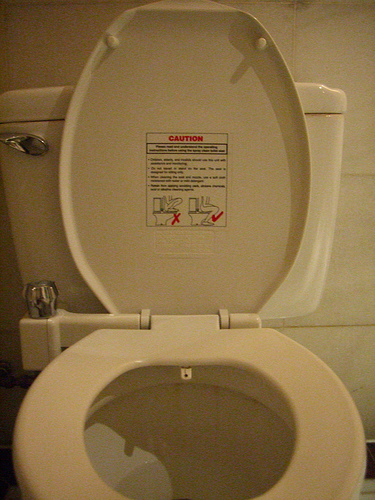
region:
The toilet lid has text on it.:
[105, 90, 255, 250]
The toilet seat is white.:
[7, 325, 362, 494]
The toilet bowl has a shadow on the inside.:
[96, 364, 283, 490]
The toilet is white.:
[4, 3, 367, 494]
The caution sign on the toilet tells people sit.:
[124, 109, 244, 247]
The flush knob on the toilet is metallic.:
[0, 124, 52, 169]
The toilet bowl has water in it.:
[90, 354, 286, 495]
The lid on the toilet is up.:
[13, 0, 359, 327]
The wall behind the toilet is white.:
[7, 8, 368, 323]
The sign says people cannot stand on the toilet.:
[132, 121, 242, 238]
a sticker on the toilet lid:
[139, 127, 235, 230]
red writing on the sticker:
[164, 132, 207, 144]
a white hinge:
[132, 304, 161, 335]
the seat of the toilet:
[12, 322, 366, 498]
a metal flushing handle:
[1, 126, 52, 161]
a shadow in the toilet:
[79, 376, 297, 497]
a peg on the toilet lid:
[103, 33, 121, 49]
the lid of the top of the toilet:
[1, 80, 352, 123]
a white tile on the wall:
[289, 4, 374, 179]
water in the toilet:
[95, 457, 263, 496]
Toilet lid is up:
[57, 0, 314, 326]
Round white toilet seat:
[12, 325, 368, 498]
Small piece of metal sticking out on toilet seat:
[177, 363, 201, 383]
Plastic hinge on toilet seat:
[133, 305, 153, 330]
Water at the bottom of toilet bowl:
[115, 447, 253, 498]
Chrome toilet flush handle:
[0, 129, 50, 159]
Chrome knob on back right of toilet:
[21, 275, 57, 322]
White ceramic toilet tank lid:
[3, 81, 350, 124]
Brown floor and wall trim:
[367, 434, 374, 480]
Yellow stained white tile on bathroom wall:
[288, 2, 372, 76]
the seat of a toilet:
[6, 313, 369, 498]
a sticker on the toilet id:
[135, 123, 237, 241]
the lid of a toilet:
[56, 1, 317, 322]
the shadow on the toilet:
[81, 391, 300, 496]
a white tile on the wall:
[282, 173, 372, 329]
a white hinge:
[217, 299, 234, 330]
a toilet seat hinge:
[132, 300, 156, 331]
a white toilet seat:
[12, 314, 368, 498]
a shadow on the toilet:
[84, 379, 299, 498]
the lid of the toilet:
[59, 2, 330, 323]